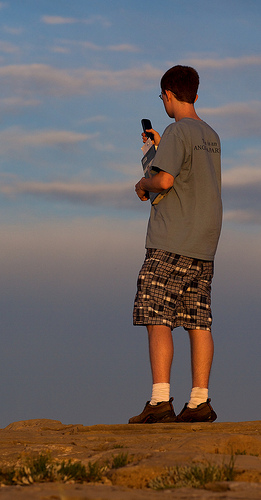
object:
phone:
[141, 118, 154, 143]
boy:
[128, 64, 222, 424]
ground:
[1, 418, 260, 498]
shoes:
[175, 397, 217, 423]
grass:
[154, 453, 248, 484]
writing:
[192, 138, 220, 154]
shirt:
[145, 119, 223, 260]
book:
[140, 144, 168, 206]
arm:
[142, 128, 180, 193]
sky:
[1, 1, 260, 423]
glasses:
[158, 92, 164, 100]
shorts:
[131, 248, 214, 331]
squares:
[164, 296, 170, 301]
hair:
[160, 64, 200, 103]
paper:
[140, 137, 153, 155]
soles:
[127, 395, 175, 424]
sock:
[149, 380, 172, 406]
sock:
[186, 386, 208, 411]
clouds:
[3, 15, 259, 214]